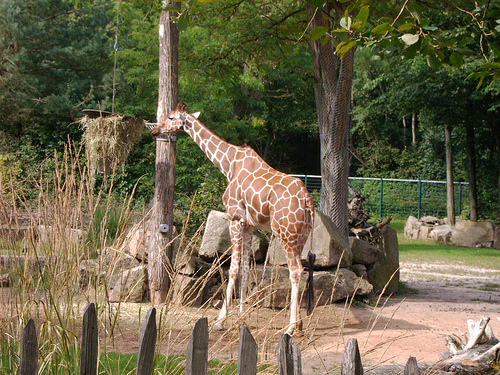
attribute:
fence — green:
[296, 174, 483, 235]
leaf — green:
[395, 31, 421, 48]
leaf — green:
[336, 12, 355, 32]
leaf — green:
[332, 35, 359, 59]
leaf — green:
[366, 20, 396, 37]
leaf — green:
[395, 18, 418, 36]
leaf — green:
[333, 32, 354, 56]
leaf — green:
[306, 23, 327, 38]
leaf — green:
[397, 20, 413, 35]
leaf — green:
[452, 34, 476, 46]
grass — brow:
[3, 102, 411, 374]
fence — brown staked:
[16, 302, 381, 374]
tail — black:
[304, 250, 315, 311]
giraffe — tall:
[143, 98, 320, 343]